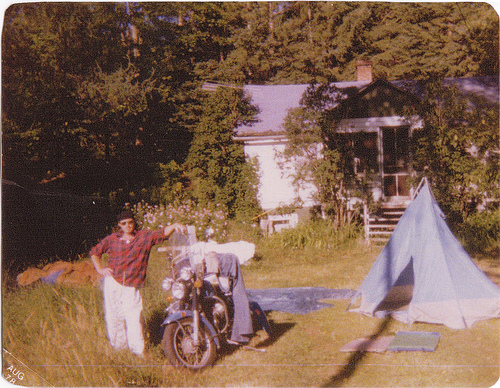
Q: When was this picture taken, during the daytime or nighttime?
A: Daytime.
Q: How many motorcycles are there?
A: One.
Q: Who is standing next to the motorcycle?
A: A man.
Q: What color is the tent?
A: Blue.